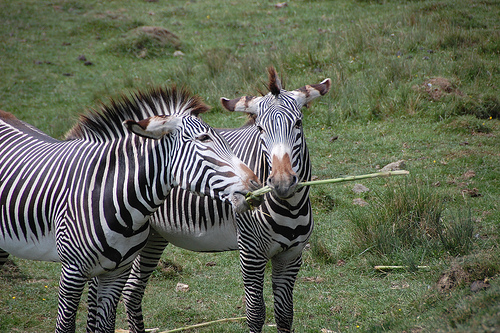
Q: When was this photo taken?
A: Day time.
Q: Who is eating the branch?
A: The zebras.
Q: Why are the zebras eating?
A: The zebras are hungry.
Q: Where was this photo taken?
A: A field.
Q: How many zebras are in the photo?
A: Two.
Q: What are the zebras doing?
A: Eating.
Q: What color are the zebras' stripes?
A: Black and white.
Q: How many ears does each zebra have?
A: Two.